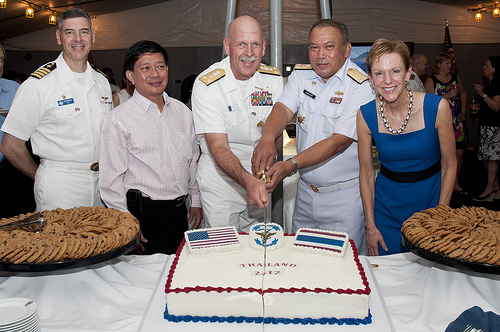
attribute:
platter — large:
[399, 191, 496, 282]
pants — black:
[106, 184, 167, 245]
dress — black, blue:
[343, 61, 481, 261]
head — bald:
[226, 12, 261, 43]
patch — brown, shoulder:
[199, 67, 225, 84]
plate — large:
[399, 227, 499, 277]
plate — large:
[1, 232, 141, 272]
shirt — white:
[4, 58, 115, 155]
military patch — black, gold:
[32, 63, 77, 85]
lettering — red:
[241, 247, 298, 284]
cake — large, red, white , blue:
[161, 220, 374, 323]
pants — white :
[11, 10, 93, 198]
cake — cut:
[166, 213, 381, 328]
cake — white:
[161, 221, 371, 277]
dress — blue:
[359, 92, 443, 254]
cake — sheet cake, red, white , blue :
[166, 225, 374, 327]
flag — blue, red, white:
[291, 226, 348, 256]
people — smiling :
[8, 22, 498, 316]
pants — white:
[281, 172, 360, 251]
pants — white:
[194, 131, 270, 231]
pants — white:
[24, 154, 103, 211]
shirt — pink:
[102, 86, 203, 219]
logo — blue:
[247, 217, 285, 249]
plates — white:
[2, 287, 42, 332]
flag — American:
[185, 225, 239, 251]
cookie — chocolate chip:
[28, 234, 45, 264]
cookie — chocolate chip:
[63, 226, 75, 262]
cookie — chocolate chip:
[40, 219, 66, 235]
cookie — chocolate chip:
[423, 236, 444, 251]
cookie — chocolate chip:
[468, 216, 484, 226]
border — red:
[163, 230, 371, 295]